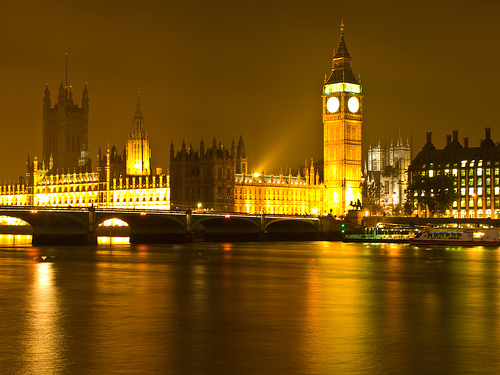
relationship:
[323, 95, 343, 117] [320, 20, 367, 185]
clock on structure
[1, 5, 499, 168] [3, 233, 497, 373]
sky above water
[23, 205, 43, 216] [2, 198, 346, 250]
signal lights on bridge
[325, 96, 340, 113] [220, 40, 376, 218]
clock on building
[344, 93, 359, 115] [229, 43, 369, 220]
clock on building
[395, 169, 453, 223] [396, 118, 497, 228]
trees in front of building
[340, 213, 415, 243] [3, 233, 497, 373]
boat in water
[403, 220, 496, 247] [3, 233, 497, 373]
boat on water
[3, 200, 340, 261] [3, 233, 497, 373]
bridge above water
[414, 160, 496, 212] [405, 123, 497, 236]
windows on building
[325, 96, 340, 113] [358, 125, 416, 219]
clock on castle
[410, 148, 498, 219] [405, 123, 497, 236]
lights on building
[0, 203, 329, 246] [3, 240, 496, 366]
bridge along river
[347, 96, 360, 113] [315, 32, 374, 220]
clock on tower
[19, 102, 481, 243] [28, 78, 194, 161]
multiple chimneys on roof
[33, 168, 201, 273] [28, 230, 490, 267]
arch under bridge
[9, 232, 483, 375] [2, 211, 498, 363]
light reflecting on water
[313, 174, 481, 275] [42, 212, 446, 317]
light on bridge